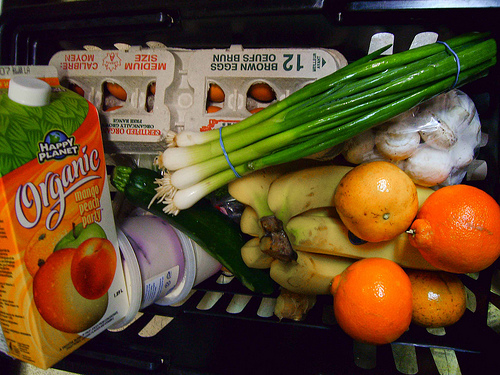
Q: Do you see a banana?
A: Yes, there is a banana.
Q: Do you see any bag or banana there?
A: Yes, there is a banana.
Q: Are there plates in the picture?
A: No, there are no plates.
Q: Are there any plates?
A: No, there are no plates.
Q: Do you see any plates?
A: No, there are no plates.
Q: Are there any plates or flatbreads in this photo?
A: No, there are no plates or flatbreads.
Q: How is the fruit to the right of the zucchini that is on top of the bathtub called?
A: The fruit is a banana.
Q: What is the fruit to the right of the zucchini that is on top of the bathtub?
A: The fruit is a banana.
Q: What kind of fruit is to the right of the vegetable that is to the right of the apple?
A: The fruit is a banana.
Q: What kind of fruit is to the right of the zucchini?
A: The fruit is a banana.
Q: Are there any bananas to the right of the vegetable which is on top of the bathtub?
A: Yes, there is a banana to the right of the zucchini.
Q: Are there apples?
A: Yes, there is an apple.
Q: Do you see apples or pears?
A: Yes, there is an apple.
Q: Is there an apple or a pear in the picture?
A: Yes, there is an apple.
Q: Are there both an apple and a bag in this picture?
A: Yes, there are both an apple and a bag.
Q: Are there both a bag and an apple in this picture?
A: Yes, there are both an apple and a bag.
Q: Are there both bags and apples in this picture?
A: Yes, there are both an apple and a bag.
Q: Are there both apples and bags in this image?
A: Yes, there are both an apple and a bag.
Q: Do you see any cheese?
A: No, there is no cheese.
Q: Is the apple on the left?
A: Yes, the apple is on the left of the image.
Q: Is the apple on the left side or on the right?
A: The apple is on the left of the image.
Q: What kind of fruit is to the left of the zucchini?
A: The fruit is an apple.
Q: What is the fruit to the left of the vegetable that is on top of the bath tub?
A: The fruit is an apple.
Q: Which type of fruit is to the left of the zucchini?
A: The fruit is an apple.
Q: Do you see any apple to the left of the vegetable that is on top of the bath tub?
A: Yes, there is an apple to the left of the zucchini.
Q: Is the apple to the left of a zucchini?
A: Yes, the apple is to the left of a zucchini.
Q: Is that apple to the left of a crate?
A: No, the apple is to the left of a zucchini.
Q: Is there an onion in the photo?
A: Yes, there are onions.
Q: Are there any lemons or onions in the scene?
A: Yes, there are onions.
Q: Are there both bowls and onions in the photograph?
A: No, there are onions but no bowls.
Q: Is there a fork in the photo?
A: No, there are no forks.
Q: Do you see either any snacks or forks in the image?
A: No, there are no forks or snacks.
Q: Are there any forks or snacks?
A: No, there are no forks or snacks.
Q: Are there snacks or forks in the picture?
A: No, there are no forks or snacks.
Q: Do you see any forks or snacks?
A: No, there are no forks or snacks.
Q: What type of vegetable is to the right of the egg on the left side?
A: The vegetables are onions.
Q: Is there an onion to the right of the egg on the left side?
A: Yes, there are onions to the right of the egg.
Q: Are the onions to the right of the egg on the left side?
A: Yes, the onions are to the right of the egg.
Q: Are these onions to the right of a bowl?
A: No, the onions are to the right of the egg.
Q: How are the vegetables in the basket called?
A: The vegetables are onions.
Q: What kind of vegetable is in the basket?
A: The vegetables are onions.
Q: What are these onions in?
A: The onions are in the basket.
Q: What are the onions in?
A: The onions are in the basket.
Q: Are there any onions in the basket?
A: Yes, there are onions in the basket.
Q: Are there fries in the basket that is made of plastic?
A: No, there are onions in the basket.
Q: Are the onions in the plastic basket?
A: Yes, the onions are in the basket.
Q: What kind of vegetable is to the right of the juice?
A: The vegetables are onions.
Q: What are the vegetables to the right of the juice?
A: The vegetables are onions.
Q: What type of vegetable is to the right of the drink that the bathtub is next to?
A: The vegetables are onions.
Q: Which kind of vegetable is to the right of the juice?
A: The vegetables are onions.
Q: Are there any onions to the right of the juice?
A: Yes, there are onions to the right of the juice.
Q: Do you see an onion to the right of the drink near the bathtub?
A: Yes, there are onions to the right of the juice.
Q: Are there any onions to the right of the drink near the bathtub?
A: Yes, there are onions to the right of the juice.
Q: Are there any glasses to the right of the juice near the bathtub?
A: No, there are onions to the right of the juice.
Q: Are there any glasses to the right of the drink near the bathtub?
A: No, there are onions to the right of the juice.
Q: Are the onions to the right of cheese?
A: No, the onions are to the right of the juice.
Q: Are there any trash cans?
A: No, there are no trash cans.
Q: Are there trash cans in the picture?
A: No, there are no trash cans.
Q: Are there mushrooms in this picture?
A: Yes, there are mushrooms.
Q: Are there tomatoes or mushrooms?
A: Yes, there are mushrooms.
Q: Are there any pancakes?
A: No, there are no pancakes.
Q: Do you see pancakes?
A: No, there are no pancakes.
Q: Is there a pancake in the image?
A: No, there are no pancakes.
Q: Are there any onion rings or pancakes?
A: No, there are no pancakes or onion rings.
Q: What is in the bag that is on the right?
A: The mushrooms are in the bag.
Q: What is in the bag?
A: The mushrooms are in the bag.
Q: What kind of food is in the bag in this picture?
A: The food is mushrooms.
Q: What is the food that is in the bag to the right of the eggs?
A: The food is mushrooms.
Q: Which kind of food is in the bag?
A: The food is mushrooms.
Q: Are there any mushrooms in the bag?
A: Yes, there are mushrooms in the bag.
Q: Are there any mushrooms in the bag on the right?
A: Yes, there are mushrooms in the bag.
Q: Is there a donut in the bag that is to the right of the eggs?
A: No, there are mushrooms in the bag.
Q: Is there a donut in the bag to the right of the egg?
A: No, there are mushrooms in the bag.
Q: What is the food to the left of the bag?
A: The food is mushrooms.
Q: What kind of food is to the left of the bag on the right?
A: The food is mushrooms.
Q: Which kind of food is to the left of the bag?
A: The food is mushrooms.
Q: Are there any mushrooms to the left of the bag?
A: Yes, there are mushrooms to the left of the bag.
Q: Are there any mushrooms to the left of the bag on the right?
A: Yes, there are mushrooms to the left of the bag.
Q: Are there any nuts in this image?
A: No, there are no nuts.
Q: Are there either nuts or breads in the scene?
A: No, there are no nuts or breads.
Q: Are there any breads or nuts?
A: No, there are no nuts or breads.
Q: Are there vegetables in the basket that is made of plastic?
A: Yes, there is a vegetable in the basket.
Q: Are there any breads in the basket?
A: No, there is a vegetable in the basket.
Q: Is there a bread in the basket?
A: No, there is a vegetable in the basket.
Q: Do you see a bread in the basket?
A: No, there is a vegetable in the basket.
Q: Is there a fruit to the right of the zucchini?
A: Yes, there are fruits to the right of the zucchini.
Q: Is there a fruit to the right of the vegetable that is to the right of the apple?
A: Yes, there are fruits to the right of the zucchini.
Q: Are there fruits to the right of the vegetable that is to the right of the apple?
A: Yes, there are fruits to the right of the zucchini.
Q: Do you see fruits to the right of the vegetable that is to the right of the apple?
A: Yes, there are fruits to the right of the zucchini.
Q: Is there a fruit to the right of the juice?
A: Yes, there are fruits to the right of the juice.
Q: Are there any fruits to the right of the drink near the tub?
A: Yes, there are fruits to the right of the juice.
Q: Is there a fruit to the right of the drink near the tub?
A: Yes, there are fruits to the right of the juice.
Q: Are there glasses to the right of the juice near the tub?
A: No, there are fruits to the right of the juice.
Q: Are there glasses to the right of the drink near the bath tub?
A: No, there are fruits to the right of the juice.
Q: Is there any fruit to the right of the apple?
A: Yes, there are fruits to the right of the apple.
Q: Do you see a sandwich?
A: No, there are no sandwiches.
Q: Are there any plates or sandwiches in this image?
A: No, there are no sandwiches or plates.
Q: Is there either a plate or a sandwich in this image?
A: No, there are no sandwiches or plates.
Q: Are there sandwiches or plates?
A: No, there are no sandwiches or plates.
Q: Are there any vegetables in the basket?
A: Yes, there is a vegetable in the basket.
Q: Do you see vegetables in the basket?
A: Yes, there is a vegetable in the basket.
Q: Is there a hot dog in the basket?
A: No, there is a vegetable in the basket.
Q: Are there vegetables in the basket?
A: Yes, there is a vegetable in the basket.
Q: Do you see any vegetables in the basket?
A: Yes, there is a vegetable in the basket.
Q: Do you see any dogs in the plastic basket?
A: No, there is a vegetable in the basket.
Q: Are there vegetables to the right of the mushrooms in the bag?
A: Yes, there is a vegetable to the right of the mushrooms.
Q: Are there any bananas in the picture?
A: Yes, there is a banana.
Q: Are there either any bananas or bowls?
A: Yes, there is a banana.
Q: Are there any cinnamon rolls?
A: No, there are no cinnamon rolls.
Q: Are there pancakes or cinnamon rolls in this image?
A: No, there are no cinnamon rolls or pancakes.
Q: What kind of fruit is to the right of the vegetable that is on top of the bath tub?
A: The fruit is a banana.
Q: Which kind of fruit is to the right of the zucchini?
A: The fruit is a banana.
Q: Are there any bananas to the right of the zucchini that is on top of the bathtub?
A: Yes, there is a banana to the right of the zucchini.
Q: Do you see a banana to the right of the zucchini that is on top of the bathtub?
A: Yes, there is a banana to the right of the zucchini.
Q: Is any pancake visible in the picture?
A: No, there are no pancakes.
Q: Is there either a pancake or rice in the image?
A: No, there are no pancakes or rice.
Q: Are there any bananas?
A: Yes, there is a banana.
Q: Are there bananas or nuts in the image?
A: Yes, there is a banana.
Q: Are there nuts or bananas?
A: Yes, there is a banana.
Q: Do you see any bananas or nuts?
A: Yes, there is a banana.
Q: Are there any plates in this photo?
A: No, there are no plates.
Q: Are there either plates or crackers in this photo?
A: No, there are no plates or crackers.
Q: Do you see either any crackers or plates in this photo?
A: No, there are no plates or crackers.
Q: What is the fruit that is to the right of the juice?
A: The fruit is a banana.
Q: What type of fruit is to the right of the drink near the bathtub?
A: The fruit is a banana.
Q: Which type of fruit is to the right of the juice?
A: The fruit is a banana.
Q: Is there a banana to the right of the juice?
A: Yes, there is a banana to the right of the juice.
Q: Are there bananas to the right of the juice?
A: Yes, there is a banana to the right of the juice.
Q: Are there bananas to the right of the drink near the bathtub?
A: Yes, there is a banana to the right of the juice.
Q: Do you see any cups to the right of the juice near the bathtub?
A: No, there is a banana to the right of the juice.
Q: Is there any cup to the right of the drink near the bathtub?
A: No, there is a banana to the right of the juice.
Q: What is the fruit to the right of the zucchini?
A: The fruit is a banana.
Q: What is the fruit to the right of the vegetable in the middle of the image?
A: The fruit is a banana.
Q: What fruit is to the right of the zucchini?
A: The fruit is a banana.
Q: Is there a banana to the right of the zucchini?
A: Yes, there is a banana to the right of the zucchini.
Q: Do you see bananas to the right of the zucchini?
A: Yes, there is a banana to the right of the zucchini.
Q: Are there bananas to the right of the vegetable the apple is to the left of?
A: Yes, there is a banana to the right of the zucchini.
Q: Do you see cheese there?
A: No, there is no cheese.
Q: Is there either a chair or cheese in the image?
A: No, there are no cheese or chairs.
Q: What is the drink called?
A: The drink is juice.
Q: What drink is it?
A: The drink is juice.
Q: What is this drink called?
A: This is juice.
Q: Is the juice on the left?
A: Yes, the juice is on the left of the image.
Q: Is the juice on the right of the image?
A: No, the juice is on the left of the image.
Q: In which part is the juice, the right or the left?
A: The juice is on the left of the image.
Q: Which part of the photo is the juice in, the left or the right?
A: The juice is on the left of the image.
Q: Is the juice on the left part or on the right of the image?
A: The juice is on the left of the image.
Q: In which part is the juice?
A: The juice is on the left of the image.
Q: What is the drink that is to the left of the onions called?
A: The drink is juice.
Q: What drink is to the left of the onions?
A: The drink is juice.